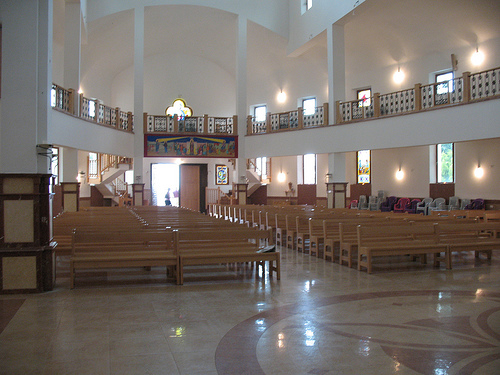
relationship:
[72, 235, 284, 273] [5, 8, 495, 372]
pew inside of church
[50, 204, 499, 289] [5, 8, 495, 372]
pew inside of church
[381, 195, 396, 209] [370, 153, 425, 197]
chair against wall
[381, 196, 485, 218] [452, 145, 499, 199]
chair against wall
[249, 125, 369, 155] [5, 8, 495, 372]
balcony inside of church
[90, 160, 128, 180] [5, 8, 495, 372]
stairs inside of church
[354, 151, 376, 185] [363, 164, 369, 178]
window with glass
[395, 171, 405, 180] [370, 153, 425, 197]
light mounted on wall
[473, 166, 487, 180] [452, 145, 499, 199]
light mounted on wall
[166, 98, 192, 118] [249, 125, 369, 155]
window above balcony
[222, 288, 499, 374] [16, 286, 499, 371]
design painted on floor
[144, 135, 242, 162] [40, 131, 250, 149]
painting hanging on balcony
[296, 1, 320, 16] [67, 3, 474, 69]
window on side of ceiling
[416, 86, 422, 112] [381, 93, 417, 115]
column supporting railing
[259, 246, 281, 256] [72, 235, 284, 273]
clothing lying on pew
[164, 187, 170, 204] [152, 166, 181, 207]
person standing in door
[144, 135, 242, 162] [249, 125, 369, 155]
painting hanging balcony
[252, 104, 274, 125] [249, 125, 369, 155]
window within balcony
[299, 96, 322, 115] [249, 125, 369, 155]
window within balcony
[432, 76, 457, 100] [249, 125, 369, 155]
window within balcony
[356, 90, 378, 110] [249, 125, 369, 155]
window within balcony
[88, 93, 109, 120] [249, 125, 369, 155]
window within balcony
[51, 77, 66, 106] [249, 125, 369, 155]
window within balcony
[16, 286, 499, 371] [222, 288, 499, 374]
floor has design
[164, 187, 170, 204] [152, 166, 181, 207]
person standing at door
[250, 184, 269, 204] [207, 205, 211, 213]
podium behind pew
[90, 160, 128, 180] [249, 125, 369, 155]
stairs ascending to balcony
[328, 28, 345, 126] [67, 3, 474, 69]
beam supporting ceiling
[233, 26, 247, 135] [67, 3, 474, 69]
beam supporting ceiling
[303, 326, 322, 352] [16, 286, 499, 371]
sunlight reflecting on floor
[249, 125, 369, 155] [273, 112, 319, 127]
balcony has railing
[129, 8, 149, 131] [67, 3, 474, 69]
beam supporting ceiling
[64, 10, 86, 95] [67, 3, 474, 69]
beam supporting ceiling